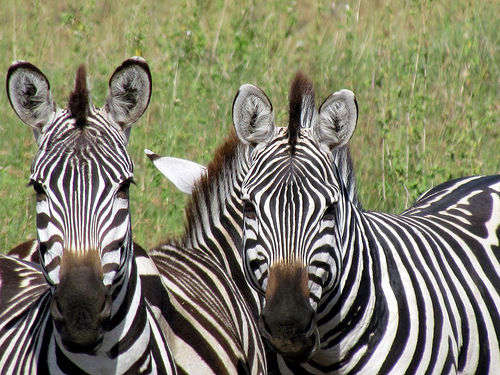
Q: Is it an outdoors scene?
A: Yes, it is outdoors.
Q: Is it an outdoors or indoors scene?
A: It is outdoors.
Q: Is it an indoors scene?
A: No, it is outdoors.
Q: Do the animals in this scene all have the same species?
A: Yes, all the animals are zebras.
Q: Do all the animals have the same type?
A: Yes, all the animals are zebras.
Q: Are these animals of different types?
A: No, all the animals are zebras.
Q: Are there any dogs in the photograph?
A: No, there are no dogs.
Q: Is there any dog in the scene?
A: No, there are no dogs.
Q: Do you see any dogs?
A: No, there are no dogs.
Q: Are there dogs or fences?
A: No, there are no dogs or fences.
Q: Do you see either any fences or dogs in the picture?
A: No, there are no dogs or fences.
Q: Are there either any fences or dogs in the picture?
A: No, there are no dogs or fences.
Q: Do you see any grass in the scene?
A: Yes, there is grass.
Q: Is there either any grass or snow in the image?
A: Yes, there is grass.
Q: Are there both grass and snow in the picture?
A: No, there is grass but no snow.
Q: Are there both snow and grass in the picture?
A: No, there is grass but no snow.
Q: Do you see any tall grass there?
A: Yes, there is tall grass.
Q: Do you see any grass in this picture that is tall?
A: Yes, there is grass that is tall.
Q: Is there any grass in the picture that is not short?
A: Yes, there is tall grass.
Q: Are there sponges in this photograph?
A: No, there are no sponges.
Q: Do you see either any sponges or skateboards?
A: No, there are no sponges or skateboards.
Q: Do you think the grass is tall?
A: Yes, the grass is tall.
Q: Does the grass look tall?
A: Yes, the grass is tall.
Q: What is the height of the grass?
A: The grass is tall.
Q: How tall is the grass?
A: The grass is tall.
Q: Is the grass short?
A: No, the grass is tall.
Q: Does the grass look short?
A: No, the grass is tall.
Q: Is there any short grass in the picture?
A: No, there is grass but it is tall.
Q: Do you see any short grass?
A: No, there is grass but it is tall.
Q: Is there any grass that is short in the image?
A: No, there is grass but it is tall.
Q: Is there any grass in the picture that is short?
A: No, there is grass but it is tall.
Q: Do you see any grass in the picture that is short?
A: No, there is grass but it is tall.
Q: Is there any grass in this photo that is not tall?
A: No, there is grass but it is tall.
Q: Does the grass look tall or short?
A: The grass is tall.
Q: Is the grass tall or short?
A: The grass is tall.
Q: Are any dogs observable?
A: No, there are no dogs.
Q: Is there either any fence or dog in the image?
A: No, there are no dogs or fences.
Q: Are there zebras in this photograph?
A: Yes, there are zebras.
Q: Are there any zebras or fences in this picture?
A: Yes, there are zebras.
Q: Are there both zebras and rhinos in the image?
A: No, there are zebras but no rhinos.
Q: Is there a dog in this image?
A: No, there are no dogs.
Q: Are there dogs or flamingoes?
A: No, there are no dogs or flamingoes.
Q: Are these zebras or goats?
A: These are zebras.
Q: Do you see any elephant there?
A: No, there are no elephants.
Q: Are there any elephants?
A: No, there are no elephants.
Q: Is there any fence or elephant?
A: No, there are no elephants or fences.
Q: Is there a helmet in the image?
A: No, there are no helmets.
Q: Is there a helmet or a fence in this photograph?
A: No, there are no helmets or fences.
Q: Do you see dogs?
A: No, there are no dogs.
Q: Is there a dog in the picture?
A: No, there are no dogs.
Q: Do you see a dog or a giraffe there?
A: No, there are no dogs or giraffes.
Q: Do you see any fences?
A: No, there are no fences.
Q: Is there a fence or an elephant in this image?
A: No, there are no fences or elephants.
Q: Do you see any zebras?
A: Yes, there is a zebra.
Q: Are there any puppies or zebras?
A: Yes, there is a zebra.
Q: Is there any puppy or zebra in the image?
A: Yes, there is a zebra.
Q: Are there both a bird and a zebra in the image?
A: No, there is a zebra but no birds.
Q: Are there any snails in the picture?
A: No, there are no snails.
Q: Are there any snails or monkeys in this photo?
A: No, there are no snails or monkeys.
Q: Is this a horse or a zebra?
A: This is a zebra.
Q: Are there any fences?
A: No, there are no fences.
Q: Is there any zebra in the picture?
A: Yes, there is a zebra.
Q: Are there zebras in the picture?
A: Yes, there is a zebra.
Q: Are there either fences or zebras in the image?
A: Yes, there is a zebra.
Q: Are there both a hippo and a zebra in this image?
A: No, there is a zebra but no hippoes.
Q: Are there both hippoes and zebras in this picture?
A: No, there is a zebra but no hippoes.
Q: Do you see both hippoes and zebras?
A: No, there is a zebra but no hippoes.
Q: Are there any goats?
A: No, there are no goats.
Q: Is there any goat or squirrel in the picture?
A: No, there are no goats or squirrels.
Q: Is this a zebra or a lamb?
A: This is a zebra.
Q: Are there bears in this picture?
A: No, there are no bears.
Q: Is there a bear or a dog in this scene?
A: No, there are no bears or dogs.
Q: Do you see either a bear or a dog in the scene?
A: No, there are no bears or dogs.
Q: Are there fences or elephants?
A: No, there are no fences or elephants.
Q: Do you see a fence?
A: No, there are no fences.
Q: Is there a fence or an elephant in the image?
A: No, there are no fences or elephants.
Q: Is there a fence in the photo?
A: No, there are no fences.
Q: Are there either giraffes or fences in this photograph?
A: No, there are no fences or giraffes.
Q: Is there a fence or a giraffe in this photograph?
A: No, there are no fences or giraffes.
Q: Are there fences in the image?
A: No, there are no fences.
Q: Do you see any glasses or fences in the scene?
A: No, there are no fences or glasses.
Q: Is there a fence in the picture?
A: No, there are no fences.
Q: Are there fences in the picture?
A: No, there are no fences.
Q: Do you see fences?
A: No, there are no fences.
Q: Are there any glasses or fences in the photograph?
A: No, there are no fences or glasses.